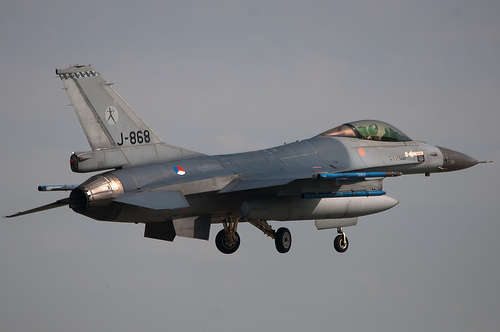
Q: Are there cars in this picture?
A: No, there are no cars.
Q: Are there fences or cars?
A: No, there are no cars or fences.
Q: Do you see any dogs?
A: No, there are no dogs.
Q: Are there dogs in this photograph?
A: No, there are no dogs.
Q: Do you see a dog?
A: No, there are no dogs.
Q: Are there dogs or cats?
A: No, there are no dogs or cats.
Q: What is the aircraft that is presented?
A: The aircraft is a jet.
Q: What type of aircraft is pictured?
A: The aircraft is a jet.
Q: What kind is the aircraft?
A: The aircraft is a jet.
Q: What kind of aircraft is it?
A: The aircraft is a jet.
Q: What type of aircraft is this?
A: This is a jet.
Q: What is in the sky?
A: The jet is in the sky.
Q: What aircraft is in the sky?
A: The aircraft is a jet.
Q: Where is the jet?
A: The jet is in the sky.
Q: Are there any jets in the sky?
A: Yes, there is a jet in the sky.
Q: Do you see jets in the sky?
A: Yes, there is a jet in the sky.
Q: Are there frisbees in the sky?
A: No, there is a jet in the sky.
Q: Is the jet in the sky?
A: Yes, the jet is in the sky.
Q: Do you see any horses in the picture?
A: No, there are no horses.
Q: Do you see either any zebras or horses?
A: No, there are no horses or zebras.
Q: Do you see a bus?
A: No, there are no buses.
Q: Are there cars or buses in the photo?
A: No, there are no buses or cars.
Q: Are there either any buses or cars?
A: No, there are no buses or cars.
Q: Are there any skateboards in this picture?
A: No, there are no skateboards.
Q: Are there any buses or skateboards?
A: No, there are no skateboards or buses.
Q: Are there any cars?
A: No, there are no cars.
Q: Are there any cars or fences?
A: No, there are no cars or fences.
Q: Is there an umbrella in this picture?
A: No, there are no umbrellas.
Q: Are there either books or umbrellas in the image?
A: No, there are no umbrellas or books.